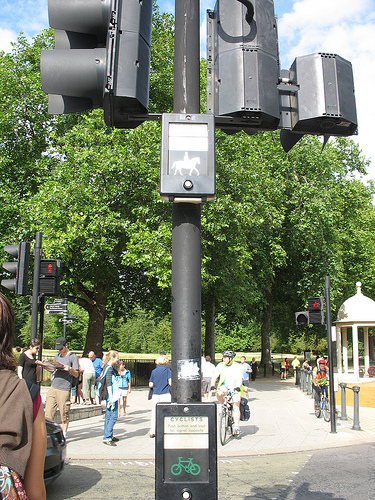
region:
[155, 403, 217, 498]
A signage showing bicycle use.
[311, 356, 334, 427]
A person riding a bicycle.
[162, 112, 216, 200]
A signage showing a person riding a horse.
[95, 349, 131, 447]
A woman standing on a pavement.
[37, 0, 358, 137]
Traffic lights on a the roadside.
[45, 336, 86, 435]
A man with a black cap.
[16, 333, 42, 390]
A woman with a black t-shirt.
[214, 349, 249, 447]
A man with a helmet riding a bicycle.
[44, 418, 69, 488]
A vehicle parked on the road.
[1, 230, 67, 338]
Traffic lights showing red to alert pedestrians.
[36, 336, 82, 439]
a man reading a map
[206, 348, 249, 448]
a man riding a bicycle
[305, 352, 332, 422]
a man riding a bicycle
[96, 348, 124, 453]
a woman standing on the sidewalk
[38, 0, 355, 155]
electronic traffic signals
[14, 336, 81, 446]
a couple looking at map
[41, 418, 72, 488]
the front of a grey car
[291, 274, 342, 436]
an electronic traffic signal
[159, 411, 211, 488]
informational sign for cyclists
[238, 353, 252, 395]
a male jogger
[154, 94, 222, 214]
a man on a horse light in city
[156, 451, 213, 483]
a lit up green bike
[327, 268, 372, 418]
a round white gazebo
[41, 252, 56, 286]
a red person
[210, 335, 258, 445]
a man riding his bike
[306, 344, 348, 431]
a person about to run into a pole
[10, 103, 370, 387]
trees that are full of green leafs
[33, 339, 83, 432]
a man reading a paper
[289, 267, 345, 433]
a black pole for bicyclists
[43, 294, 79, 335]
black and white street signs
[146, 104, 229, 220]
box on black pole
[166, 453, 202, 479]
illustration of green bike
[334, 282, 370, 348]
white dome on columns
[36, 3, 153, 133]
side of black traffic light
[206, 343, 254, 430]
person in helmet on bike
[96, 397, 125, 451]
blue jeans on standing person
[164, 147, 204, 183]
horse figure on box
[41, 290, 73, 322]
signs on black pole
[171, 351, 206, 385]
sticker on metal pole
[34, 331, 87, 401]
man looking at paper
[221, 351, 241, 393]
this is a man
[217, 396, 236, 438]
this is a bike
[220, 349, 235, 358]
he is wearing a helmet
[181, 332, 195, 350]
the pole is black in color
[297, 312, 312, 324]
the light is off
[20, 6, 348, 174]
this is a traffic light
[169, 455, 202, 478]
a bike is drawn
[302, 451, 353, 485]
the road is clear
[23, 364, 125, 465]
people are many in the road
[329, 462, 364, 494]
road is tarmacked